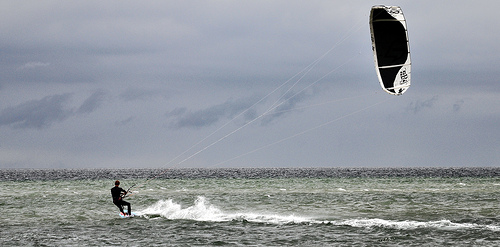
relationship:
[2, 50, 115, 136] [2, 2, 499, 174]
cloud in sky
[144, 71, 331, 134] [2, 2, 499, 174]
cloud in sky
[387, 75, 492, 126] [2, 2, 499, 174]
cloud in sky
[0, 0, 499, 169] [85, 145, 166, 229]
air above man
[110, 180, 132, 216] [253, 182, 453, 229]
man in water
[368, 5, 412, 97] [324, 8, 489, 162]
kite in air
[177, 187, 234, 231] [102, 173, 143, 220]
water next to man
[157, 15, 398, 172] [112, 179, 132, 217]
rope held by man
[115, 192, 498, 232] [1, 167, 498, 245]
waves in water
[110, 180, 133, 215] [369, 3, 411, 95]
man flying kite